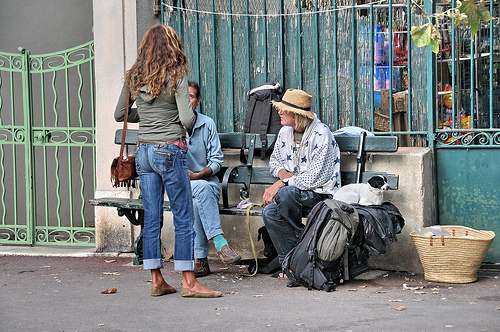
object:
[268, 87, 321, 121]
hat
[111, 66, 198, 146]
hoodie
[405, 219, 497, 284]
basket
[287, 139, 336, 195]
longsleeve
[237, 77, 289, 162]
backpack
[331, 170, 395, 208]
dog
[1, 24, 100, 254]
gate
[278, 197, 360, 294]
pack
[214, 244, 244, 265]
loafer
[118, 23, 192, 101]
hair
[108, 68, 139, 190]
purse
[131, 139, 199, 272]
jeans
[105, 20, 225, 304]
woman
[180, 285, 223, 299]
flats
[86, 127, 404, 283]
bench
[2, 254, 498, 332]
sidewalk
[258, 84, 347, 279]
person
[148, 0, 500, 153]
railing